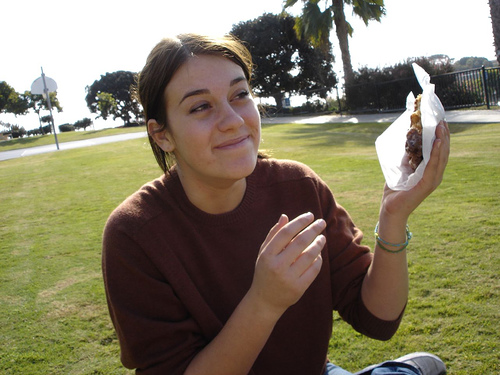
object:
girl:
[98, 32, 452, 375]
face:
[166, 54, 264, 180]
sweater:
[98, 158, 405, 375]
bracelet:
[381, 244, 406, 256]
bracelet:
[374, 218, 412, 253]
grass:
[437, 249, 475, 304]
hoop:
[29, 74, 58, 96]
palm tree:
[305, 2, 363, 82]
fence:
[455, 71, 498, 105]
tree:
[352, 66, 390, 111]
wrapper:
[376, 133, 397, 177]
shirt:
[262, 184, 312, 209]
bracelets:
[373, 227, 416, 259]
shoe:
[401, 351, 449, 374]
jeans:
[326, 359, 417, 374]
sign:
[284, 97, 294, 107]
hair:
[154, 45, 190, 61]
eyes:
[189, 100, 214, 114]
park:
[11, 9, 500, 364]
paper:
[404, 60, 442, 112]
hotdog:
[404, 94, 427, 174]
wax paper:
[413, 62, 434, 109]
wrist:
[231, 287, 286, 327]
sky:
[124, 1, 202, 25]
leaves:
[293, 12, 333, 51]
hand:
[252, 211, 328, 308]